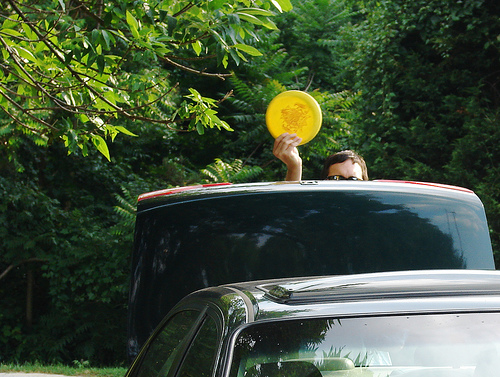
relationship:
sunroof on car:
[261, 264, 498, 304] [95, 154, 493, 374]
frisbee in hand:
[256, 75, 331, 147] [266, 124, 314, 169]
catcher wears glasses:
[273, 132, 369, 181] [326, 175, 364, 181]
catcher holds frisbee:
[273, 132, 369, 181] [266, 87, 323, 148]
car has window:
[126, 179, 493, 375] [175, 320, 221, 372]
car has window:
[126, 179, 493, 375] [131, 309, 197, 371]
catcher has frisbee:
[273, 132, 369, 181] [264, 90, 325, 145]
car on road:
[126, 179, 493, 375] [0, 370, 75, 375]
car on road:
[123, 268, 500, 377] [0, 370, 75, 375]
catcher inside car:
[273, 132, 369, 181] [126, 179, 493, 375]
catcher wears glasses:
[273, 132, 369, 181] [324, 168, 361, 185]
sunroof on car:
[264, 269, 500, 303] [126, 179, 493, 375]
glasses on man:
[326, 175, 364, 181] [269, 127, 372, 181]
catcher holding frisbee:
[273, 132, 369, 181] [266, 87, 323, 148]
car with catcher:
[126, 179, 493, 375] [273, 132, 369, 181]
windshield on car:
[221, 308, 498, 375] [126, 179, 493, 375]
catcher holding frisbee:
[273, 132, 369, 181] [264, 88, 322, 143]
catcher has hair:
[273, 132, 369, 181] [326, 149, 366, 179]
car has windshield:
[126, 179, 493, 375] [229, 303, 499, 373]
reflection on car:
[244, 172, 499, 265] [126, 179, 493, 375]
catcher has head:
[273, 132, 369, 181] [318, 122, 369, 198]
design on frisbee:
[280, 100, 308, 133] [266, 87, 323, 148]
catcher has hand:
[273, 132, 369, 181] [272, 132, 302, 169]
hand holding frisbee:
[272, 132, 302, 169] [266, 85, 326, 152]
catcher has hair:
[273, 132, 369, 181] [322, 151, 367, 176]